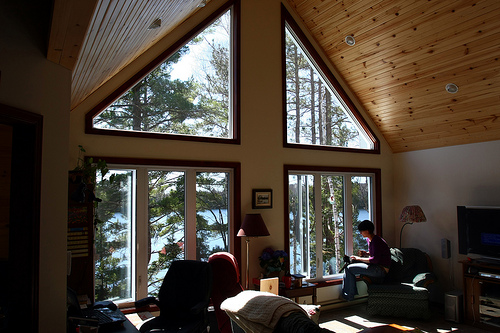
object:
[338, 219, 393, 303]
girl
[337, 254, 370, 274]
cat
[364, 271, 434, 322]
chair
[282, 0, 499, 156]
ceiling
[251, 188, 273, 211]
picture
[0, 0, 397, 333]
wall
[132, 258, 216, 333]
seat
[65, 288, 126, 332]
laptop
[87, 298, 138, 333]
table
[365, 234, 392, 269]
shirt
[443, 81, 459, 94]
lights